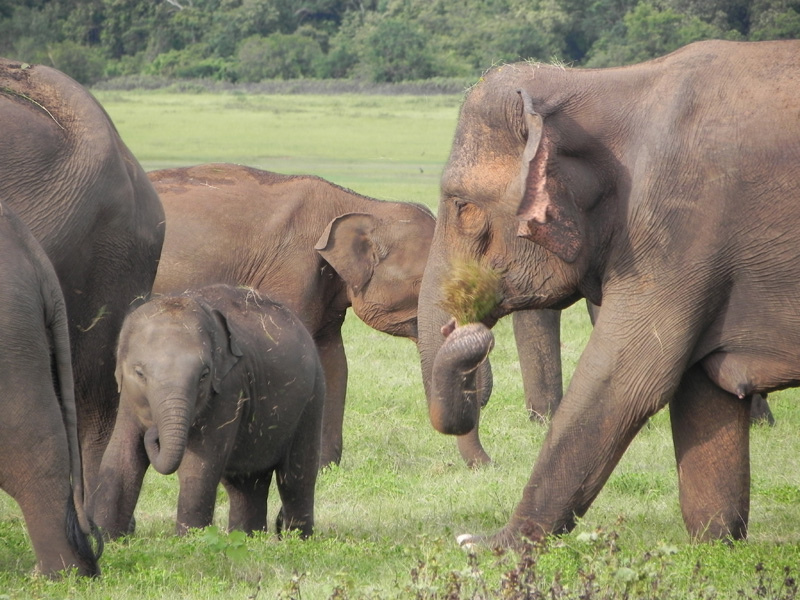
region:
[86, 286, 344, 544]
A baby elephant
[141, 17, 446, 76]
An area of trees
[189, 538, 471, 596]
A grassy patch of ground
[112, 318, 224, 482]
A baby elephant's head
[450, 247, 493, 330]
A clump of grass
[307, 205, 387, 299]
An elephant ear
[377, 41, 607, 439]
The profile of an adult elephant head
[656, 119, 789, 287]
Gray wrinkled elephant skin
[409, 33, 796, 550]
a large grey elephant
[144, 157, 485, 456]
a large grey elephant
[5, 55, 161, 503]
a large grey elephant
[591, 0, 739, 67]
a tree in the woods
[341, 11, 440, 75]
a tree in the woods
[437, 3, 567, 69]
a tree in the woods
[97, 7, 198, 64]
a tree in the woods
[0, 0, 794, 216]
forest behind green field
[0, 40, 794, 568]
four adult elephants with one baby elephant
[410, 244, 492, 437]
elephant holds clump of grass in trunk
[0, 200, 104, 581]
rear leg and tail of elephant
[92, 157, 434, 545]
baby elephant in front of adult elephant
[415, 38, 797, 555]
adult elephant has milk-swollen breast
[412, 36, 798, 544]
elephant is eating grass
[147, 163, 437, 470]
elephant has right ear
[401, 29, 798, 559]
elephant eating grass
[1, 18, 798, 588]
several elephants in the grass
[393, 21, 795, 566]
elephant facing towards the left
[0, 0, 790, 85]
row of trees and bushes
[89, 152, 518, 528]
elephant facing towards the right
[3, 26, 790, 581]
family of elephants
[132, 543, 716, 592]
green grass and flowers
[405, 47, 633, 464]
elephant curling a trunk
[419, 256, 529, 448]
grass in an elephant's trunk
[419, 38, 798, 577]
large gray and brown elephant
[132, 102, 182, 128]
tall green and yellow grass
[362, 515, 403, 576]
tall green and yellow grass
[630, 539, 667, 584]
tall green and yellow grass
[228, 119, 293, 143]
tall green and yellow grass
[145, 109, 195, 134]
tall green and yellow grass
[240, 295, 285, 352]
grass on the baby elephant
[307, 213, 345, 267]
folded over ear on the elephant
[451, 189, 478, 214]
eye of the elephant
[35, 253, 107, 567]
tail on the elephant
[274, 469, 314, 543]
leg of the baby elephant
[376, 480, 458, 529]
green grass on the ground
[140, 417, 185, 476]
wrinkly trunk on the baby elephant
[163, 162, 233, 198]
black spot on the back of the elephant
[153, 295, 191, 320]
dirt spot on top of the baby elephant's head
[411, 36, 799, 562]
large grey brown elephant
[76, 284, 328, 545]
small grey brown elephant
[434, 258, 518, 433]
elephant has grass in his trunk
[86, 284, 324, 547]
baby elephant in the middle of elephants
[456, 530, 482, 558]
toe nails on the elephant's foot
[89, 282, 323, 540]
a baby elephant in the middle of some grown up ones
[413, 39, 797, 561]
an elephant using it's trunk to eat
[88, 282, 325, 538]
a young elephant putting it's trunk in it's mouth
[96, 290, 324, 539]
an elephant with dead grass stuck to it's flank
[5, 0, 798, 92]
a tree line on the edge of a field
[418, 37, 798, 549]
an elephant taking a step forward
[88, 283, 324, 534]
the smallest elephant in a group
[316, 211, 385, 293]
the right ear of an elephant